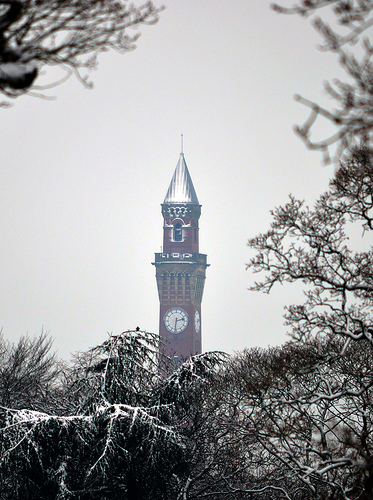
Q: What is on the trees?
A: Snow.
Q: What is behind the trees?
A: A clocktower.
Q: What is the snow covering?
A: The trees.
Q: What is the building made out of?
A: Brick.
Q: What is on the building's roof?
A: Snow.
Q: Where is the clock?
A: On the building.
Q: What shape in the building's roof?
A: Pointed.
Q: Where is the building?
A: Behind the trees.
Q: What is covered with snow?
A: Tree.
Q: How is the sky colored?
A: White.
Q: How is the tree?
A: Branchey.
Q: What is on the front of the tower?
A: Clock.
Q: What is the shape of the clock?
A: Round.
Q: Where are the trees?
A: Foreground.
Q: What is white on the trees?
A: Snow.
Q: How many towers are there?
A: One.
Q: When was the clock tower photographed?
A: Daytime.